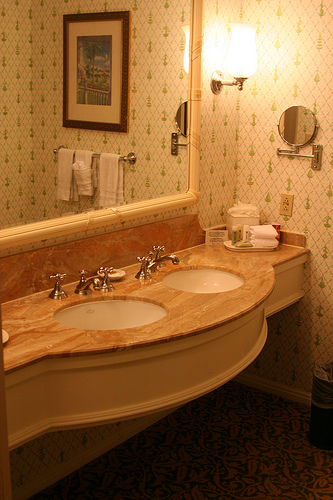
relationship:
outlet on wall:
[277, 190, 297, 222] [201, 3, 332, 400]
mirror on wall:
[0, 0, 205, 251] [201, 3, 332, 400]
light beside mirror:
[208, 23, 259, 95] [0, 0, 205, 251]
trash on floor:
[308, 361, 332, 445] [28, 378, 331, 498]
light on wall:
[208, 23, 259, 95] [201, 3, 332, 400]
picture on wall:
[61, 10, 133, 134] [201, 3, 332, 400]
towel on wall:
[96, 150, 125, 210] [201, 3, 332, 400]